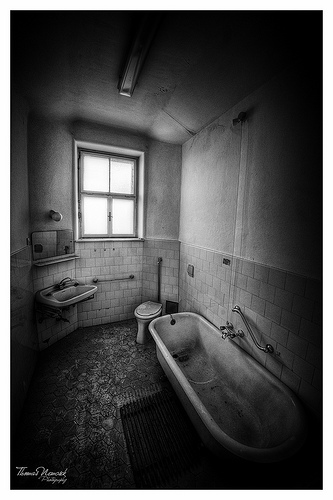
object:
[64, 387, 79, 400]
tile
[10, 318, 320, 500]
floor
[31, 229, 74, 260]
mirror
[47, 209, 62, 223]
light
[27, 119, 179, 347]
wall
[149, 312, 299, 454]
bathtub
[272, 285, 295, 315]
tile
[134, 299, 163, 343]
toilet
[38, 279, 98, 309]
sink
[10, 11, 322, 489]
bathroom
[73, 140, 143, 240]
window